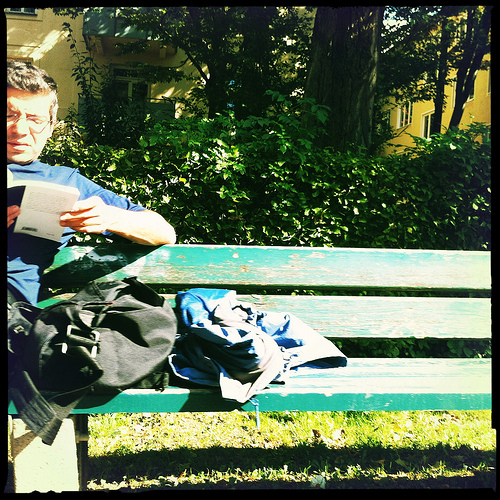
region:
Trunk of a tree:
[294, 3, 384, 176]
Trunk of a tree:
[455, 35, 492, 117]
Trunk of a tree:
[422, 35, 452, 148]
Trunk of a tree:
[194, 25, 234, 151]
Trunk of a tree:
[196, 32, 283, 231]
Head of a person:
[4, 53, 59, 171]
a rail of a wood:
[47, 230, 498, 301]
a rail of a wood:
[73, 290, 497, 348]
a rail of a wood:
[66, 335, 498, 404]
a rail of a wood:
[11, 363, 497, 430]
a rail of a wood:
[98, 342, 495, 382]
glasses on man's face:
[2, 108, 72, 133]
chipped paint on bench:
[163, 256, 248, 276]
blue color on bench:
[296, 383, 443, 425]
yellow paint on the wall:
[460, 103, 494, 119]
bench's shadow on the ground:
[234, 431, 431, 477]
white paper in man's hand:
[13, 173, 98, 265]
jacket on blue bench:
[182, 284, 338, 408]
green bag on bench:
[41, 273, 176, 391]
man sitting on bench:
[6, 65, 178, 304]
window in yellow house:
[92, 63, 167, 123]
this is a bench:
[6, 169, 485, 490]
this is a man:
[10, 46, 153, 477]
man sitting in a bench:
[8, 42, 485, 482]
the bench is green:
[15, 180, 494, 459]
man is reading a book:
[0, 45, 194, 343]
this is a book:
[0, 145, 122, 260]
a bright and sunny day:
[16, 16, 498, 494]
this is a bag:
[15, 251, 190, 424]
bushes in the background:
[43, 88, 495, 363]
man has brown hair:
[6, 48, 57, 98]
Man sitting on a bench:
[0, 46, 187, 446]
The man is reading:
[2, 45, 203, 477]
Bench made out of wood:
[14, 211, 485, 422]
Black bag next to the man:
[39, 265, 201, 419]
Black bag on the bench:
[22, 252, 211, 423]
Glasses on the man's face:
[0, 102, 67, 140]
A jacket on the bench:
[155, 271, 367, 406]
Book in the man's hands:
[0, 168, 106, 253]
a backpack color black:
[9, 270, 182, 452]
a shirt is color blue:
[167, 282, 349, 412]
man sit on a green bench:
[8, 45, 490, 450]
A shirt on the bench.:
[167, 279, 355, 405]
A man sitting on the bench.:
[7, 58, 199, 468]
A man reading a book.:
[8, 59, 178, 448]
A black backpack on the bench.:
[11, 263, 196, 425]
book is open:
[5, 165, 81, 242]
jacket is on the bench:
[171, 290, 352, 404]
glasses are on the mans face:
[6, 110, 57, 132]